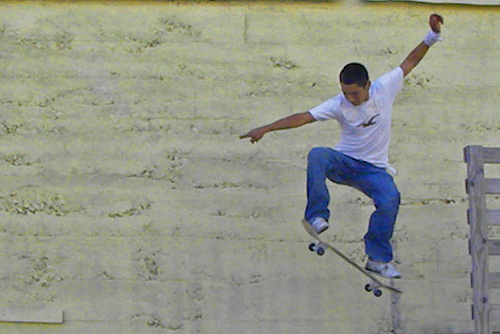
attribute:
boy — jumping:
[234, 12, 446, 302]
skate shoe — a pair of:
[363, 256, 402, 281]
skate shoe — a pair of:
[312, 212, 331, 234]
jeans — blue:
[299, 147, 400, 276]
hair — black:
[336, 61, 370, 88]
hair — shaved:
[332, 57, 372, 89]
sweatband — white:
[423, 25, 441, 45]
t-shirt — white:
[307, 66, 404, 178]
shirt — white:
[268, 79, 447, 186]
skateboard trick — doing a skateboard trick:
[287, 223, 424, 332]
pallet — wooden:
[463, 145, 499, 331]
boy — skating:
[277, 89, 423, 303]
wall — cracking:
[4, 4, 498, 332]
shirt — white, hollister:
[326, 72, 407, 172]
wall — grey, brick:
[7, 12, 288, 310]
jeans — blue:
[302, 145, 399, 264]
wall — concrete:
[52, 73, 254, 302]